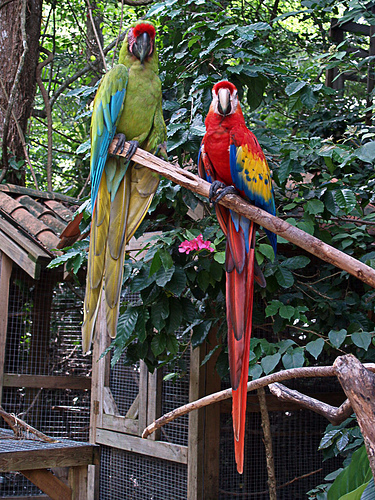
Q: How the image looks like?
A: Colorful.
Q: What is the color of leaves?
A: Green.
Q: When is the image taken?
A: When parrots are on tree.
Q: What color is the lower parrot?
A: Red, blue, yellow, and white.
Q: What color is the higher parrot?
A: Green, blue, red, and yellow.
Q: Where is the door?
A: On the bird cage.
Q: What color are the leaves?
A: Green.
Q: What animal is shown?
A: Parrot.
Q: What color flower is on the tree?
A: Pink.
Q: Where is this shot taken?
A: Zoo.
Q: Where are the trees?
A: Behind the birds.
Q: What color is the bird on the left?
A: Green.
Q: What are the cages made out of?
A: Wood and wire.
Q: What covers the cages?
A: A roof.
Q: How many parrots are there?
A: Two.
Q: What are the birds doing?
A: Perching.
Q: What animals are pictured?
A: Birds.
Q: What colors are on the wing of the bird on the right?
A: Red, blue, and yellow.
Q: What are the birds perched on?
A: A tree branch.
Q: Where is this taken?
A: At a zoo.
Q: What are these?
A: Birds.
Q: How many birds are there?
A: 2.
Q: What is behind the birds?
A: Trees.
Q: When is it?
A: Day time.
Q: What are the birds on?
A: Branch.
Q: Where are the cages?
A: Behind the birds.